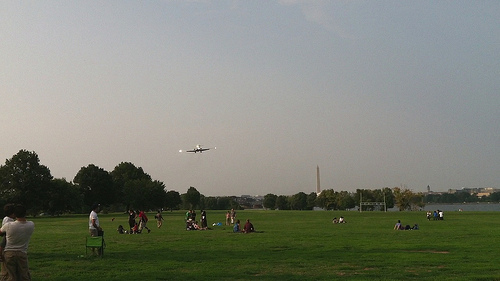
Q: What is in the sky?
A: A plane.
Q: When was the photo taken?
A: Evening.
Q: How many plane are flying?
A: One.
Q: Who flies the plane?
A: A pilot.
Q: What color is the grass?
A: Green.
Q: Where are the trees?
A: In the back.